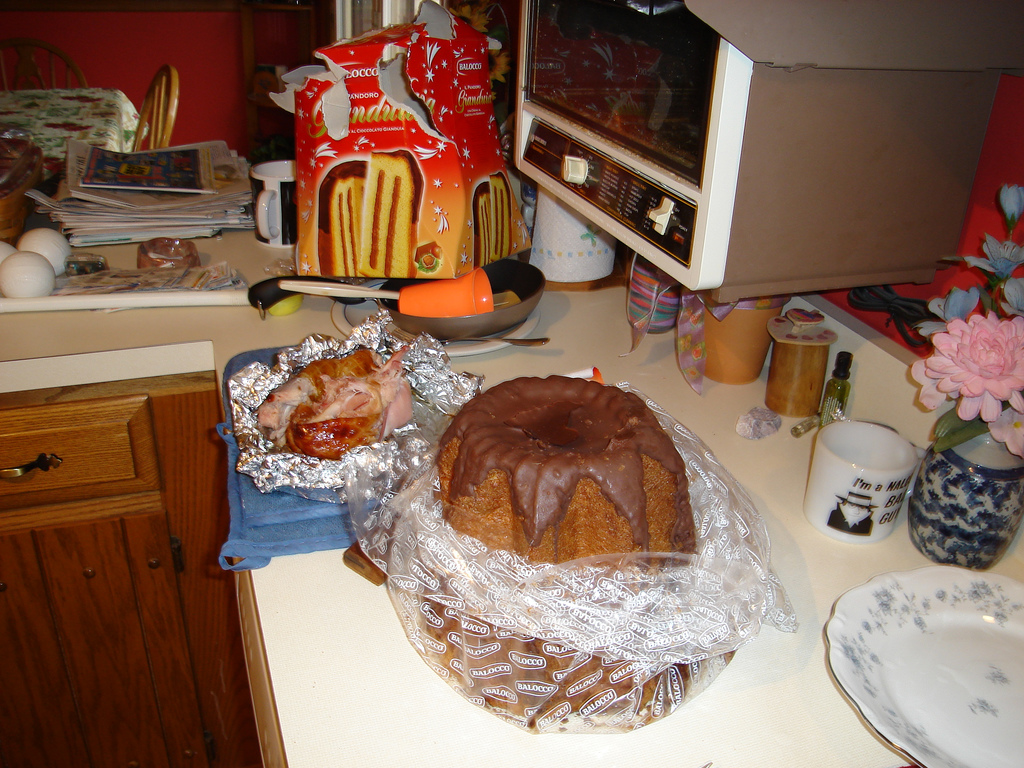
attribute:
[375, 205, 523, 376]
cup — orange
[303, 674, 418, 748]
counter — white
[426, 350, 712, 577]
cake — brown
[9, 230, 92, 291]
egg — white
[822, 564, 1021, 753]
plate — white, floral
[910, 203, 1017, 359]
flowers — fake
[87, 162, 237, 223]
newspaper — stacked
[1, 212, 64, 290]
ball — white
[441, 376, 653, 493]
frosting — chocolate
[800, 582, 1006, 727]
plate — fancy, white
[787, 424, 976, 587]
mug — white, black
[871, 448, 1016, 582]
vase — blue, white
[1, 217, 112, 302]
eggs — white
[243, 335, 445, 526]
turkey — leftover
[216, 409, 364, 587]
oven mitts — blue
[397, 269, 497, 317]
drinking cup — plastic, orange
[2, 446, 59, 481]
handle — bronze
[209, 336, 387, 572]
towel — blue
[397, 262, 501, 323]
cup — orange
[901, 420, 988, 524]
vase — blue, white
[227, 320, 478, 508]
aluminum — silver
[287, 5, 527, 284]
box — torn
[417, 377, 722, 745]
cake — golden brown